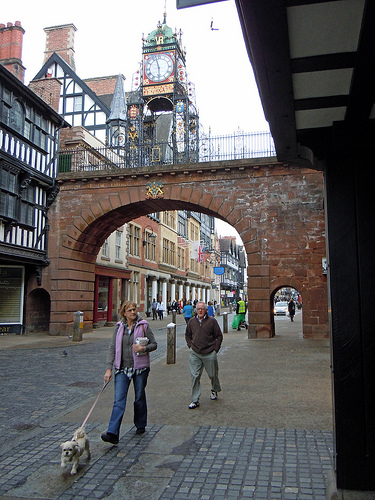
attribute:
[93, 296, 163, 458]
woman — older, standing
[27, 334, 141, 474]
street — wet, red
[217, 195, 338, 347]
wall — red, brick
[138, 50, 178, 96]
clock — roman, small, white, black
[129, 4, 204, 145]
tower — tall